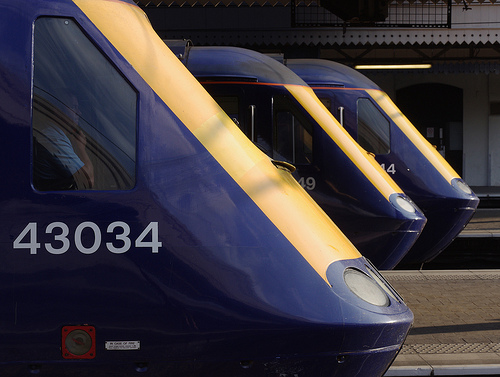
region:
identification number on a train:
[13, 218, 165, 256]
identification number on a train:
[296, 176, 317, 191]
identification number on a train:
[380, 162, 396, 175]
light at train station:
[353, 60, 433, 72]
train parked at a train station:
[261, 53, 478, 268]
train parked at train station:
[166, 41, 427, 268]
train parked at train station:
[0, 2, 415, 376]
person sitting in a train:
[27, 83, 96, 192]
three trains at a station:
[1, 1, 479, 374]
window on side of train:
[29, 12, 141, 196]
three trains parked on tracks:
[2, 0, 484, 372]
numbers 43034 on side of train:
[0, 207, 176, 285]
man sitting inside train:
[16, 78, 106, 193]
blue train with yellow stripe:
[1, 2, 411, 372]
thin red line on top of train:
[183, 67, 301, 94]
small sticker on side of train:
[100, 333, 144, 358]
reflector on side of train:
[42, 319, 111, 371]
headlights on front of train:
[315, 242, 434, 317]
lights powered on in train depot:
[335, 53, 433, 93]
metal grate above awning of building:
[270, 0, 491, 43]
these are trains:
[24, 36, 447, 346]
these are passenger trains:
[34, 33, 463, 332]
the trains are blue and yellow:
[10, 41, 370, 373]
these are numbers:
[5, 201, 229, 307]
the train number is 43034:
[26, 207, 198, 262]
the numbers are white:
[0, 206, 221, 266]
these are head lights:
[310, 223, 430, 339]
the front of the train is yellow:
[133, 19, 338, 279]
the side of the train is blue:
[99, 273, 325, 372]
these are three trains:
[67, 41, 472, 312]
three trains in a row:
[125, 30, 455, 350]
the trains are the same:
[70, 7, 450, 367]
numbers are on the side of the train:
[1, 190, 201, 291]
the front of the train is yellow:
[275, 65, 431, 235]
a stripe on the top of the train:
[313, 60, 398, 115]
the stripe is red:
[300, 65, 386, 119]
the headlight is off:
[335, 244, 406, 320]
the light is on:
[311, 37, 448, 97]